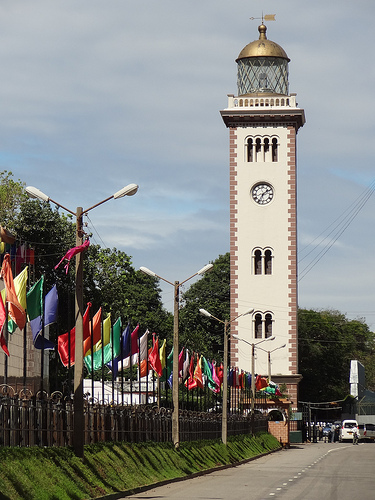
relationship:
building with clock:
[219, 4, 304, 440] [253, 180, 277, 206]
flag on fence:
[107, 311, 150, 349] [3, 344, 283, 463]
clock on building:
[245, 177, 277, 211] [193, 13, 336, 456]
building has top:
[210, 4, 319, 458] [228, 9, 292, 107]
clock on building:
[245, 177, 277, 211] [219, 4, 304, 440]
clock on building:
[245, 177, 277, 211] [212, 9, 318, 449]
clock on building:
[245, 177, 277, 211] [219, 2, 321, 311]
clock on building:
[245, 177, 277, 211] [216, 90, 307, 447]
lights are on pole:
[17, 158, 261, 332] [174, 285, 179, 444]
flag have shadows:
[107, 311, 150, 349] [2, 429, 280, 499]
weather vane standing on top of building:
[246, 8, 276, 27] [219, 25, 309, 381]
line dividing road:
[275, 485, 281, 491] [104, 437, 363, 497]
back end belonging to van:
[341, 419, 360, 440] [338, 419, 361, 441]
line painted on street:
[275, 485, 281, 491] [107, 439, 363, 498]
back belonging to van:
[339, 420, 358, 440] [336, 420, 362, 442]